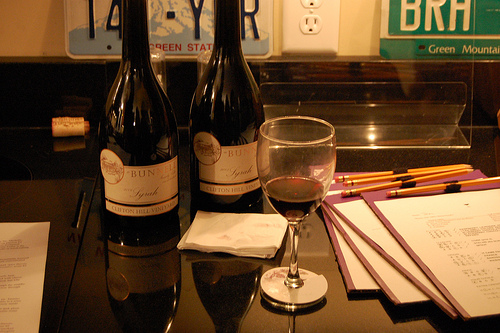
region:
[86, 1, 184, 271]
bottle of wine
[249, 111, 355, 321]
glass of wine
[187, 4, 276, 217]
bottle of wine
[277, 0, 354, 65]
white wall receptacle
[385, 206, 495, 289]
paper with black print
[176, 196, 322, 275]
small white drink napkins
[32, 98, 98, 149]
cork off wine bottle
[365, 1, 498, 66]
green and white license plate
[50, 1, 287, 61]
blue and white license plate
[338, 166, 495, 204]
yellow pencils with erasers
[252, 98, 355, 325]
wine glass with a little red wine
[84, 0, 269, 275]
two wine bottles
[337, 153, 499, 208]
yellow pencils sharpened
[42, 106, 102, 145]
brown wine cork on counter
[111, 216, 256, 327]
reflection of wine bottles on table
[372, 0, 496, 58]
green license hung on wall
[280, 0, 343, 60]
white wall outlet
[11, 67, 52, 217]
shiny black counter top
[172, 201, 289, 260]
white napkin in front of wine bottles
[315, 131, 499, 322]
set of four folders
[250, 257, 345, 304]
stem of clear wine glass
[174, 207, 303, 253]
white napkin on table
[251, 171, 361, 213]
brown liquid in glass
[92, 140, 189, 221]
white label on wine bottle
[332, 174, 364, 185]
red erasers on yellow pencil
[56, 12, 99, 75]
section of white and blue license plate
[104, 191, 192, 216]
black line on wine bottle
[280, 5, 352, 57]
white electrical wall plug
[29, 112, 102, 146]
white wine cork bottle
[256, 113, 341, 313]
glass of red wine on black table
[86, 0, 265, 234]
two bottles of red wine onblack table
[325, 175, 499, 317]
white menus trimmed in red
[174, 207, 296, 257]
white napkins on black table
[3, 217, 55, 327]
white paper on black table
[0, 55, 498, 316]
black shiny table in room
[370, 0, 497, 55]
green license plate on wall with white letters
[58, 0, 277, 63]
white license plate with dark blue numbers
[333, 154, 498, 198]
yellow pencils on black table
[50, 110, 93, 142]
beige cork on black table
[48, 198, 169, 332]
Shiny black table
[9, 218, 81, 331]
White paper on a table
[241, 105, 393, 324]
Wine glass with red wine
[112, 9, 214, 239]
Bottle of wine on a table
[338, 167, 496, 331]
Purple clipboards with a pencil and paper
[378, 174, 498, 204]
Pencil on a clipboard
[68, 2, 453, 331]
Two bottles of wine on a table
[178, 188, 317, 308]
White napkin on a black table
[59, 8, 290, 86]
Washington license plate against a wall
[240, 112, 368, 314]
Wine glass sitting on a black table